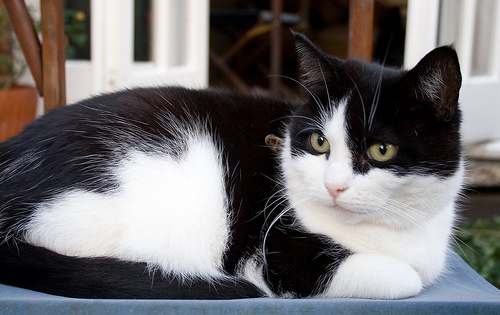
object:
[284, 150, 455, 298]
hair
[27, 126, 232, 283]
hair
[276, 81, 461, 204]
face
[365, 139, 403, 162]
eye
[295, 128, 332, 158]
eye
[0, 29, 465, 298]
cat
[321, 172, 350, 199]
nose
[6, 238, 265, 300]
tail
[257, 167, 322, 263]
whiskers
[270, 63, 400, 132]
whiskers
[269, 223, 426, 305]
paw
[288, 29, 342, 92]
ear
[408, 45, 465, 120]
ear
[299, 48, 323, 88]
hairs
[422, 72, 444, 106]
hairs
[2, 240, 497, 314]
chair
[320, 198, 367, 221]
mouth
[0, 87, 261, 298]
hind quarters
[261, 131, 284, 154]
collar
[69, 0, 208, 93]
door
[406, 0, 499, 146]
door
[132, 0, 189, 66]
window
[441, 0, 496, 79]
window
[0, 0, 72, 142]
beam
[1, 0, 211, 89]
wall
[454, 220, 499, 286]
foilag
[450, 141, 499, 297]
ground